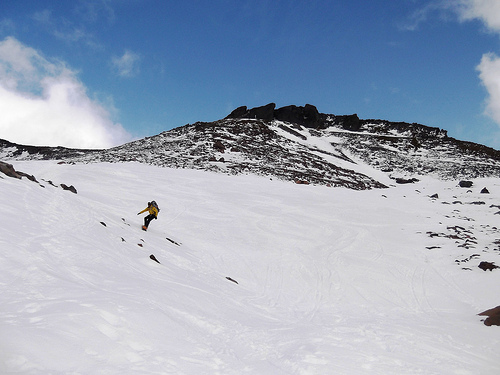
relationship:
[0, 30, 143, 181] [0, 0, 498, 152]
clouds in sky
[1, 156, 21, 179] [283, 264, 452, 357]
rock in snow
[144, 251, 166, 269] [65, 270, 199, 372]
rock in snow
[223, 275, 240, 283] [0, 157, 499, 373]
black rock in snow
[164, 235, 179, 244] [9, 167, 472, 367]
black rock in snow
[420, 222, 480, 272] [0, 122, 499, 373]
rocks in snow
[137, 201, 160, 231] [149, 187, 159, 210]
hiker wearing backpack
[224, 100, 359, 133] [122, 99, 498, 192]
rocks on summit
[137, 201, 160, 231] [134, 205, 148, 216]
hiker has outstretched arm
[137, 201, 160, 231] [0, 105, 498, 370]
hiker on hill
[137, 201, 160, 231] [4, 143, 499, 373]
hiker scaling hillside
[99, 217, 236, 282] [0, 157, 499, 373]
rock pieces in snow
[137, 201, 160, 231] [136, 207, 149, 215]
hiker swinging out arm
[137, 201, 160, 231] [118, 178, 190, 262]
hiker wearing coat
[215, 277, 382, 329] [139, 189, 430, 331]
tracks in snow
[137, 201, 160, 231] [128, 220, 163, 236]
hiker has snowboard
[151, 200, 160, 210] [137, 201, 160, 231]
backpack on back of hiker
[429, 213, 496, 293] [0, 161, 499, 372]
rocks next to hillside